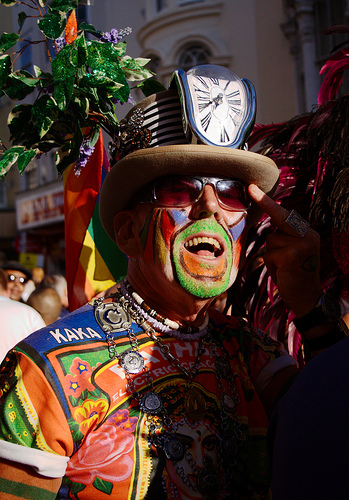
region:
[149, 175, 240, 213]
A man wearing sunglasses.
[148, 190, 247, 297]
The man face is painted.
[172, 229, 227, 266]
The man mouth is open.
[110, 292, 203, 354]
Beaded necklace around the man neck.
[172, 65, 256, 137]
A clock on the man head.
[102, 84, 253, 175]
The man is wearing a hat.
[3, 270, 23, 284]
The man is wearing glasses.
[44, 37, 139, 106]
Leaves on top of the hat.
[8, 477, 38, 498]
A green line on the man arm.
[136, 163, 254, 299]
Paint on a man's face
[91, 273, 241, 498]
Four necklaces on a man's neck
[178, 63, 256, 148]
Blue framed white analog clock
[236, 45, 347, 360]
Dark pink feather headdress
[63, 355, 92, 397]
Two peach flowers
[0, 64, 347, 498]
Man wearing colorful clothing and a hat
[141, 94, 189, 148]
Black and white stripes around a hat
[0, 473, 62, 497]
Green painted stripe on an arm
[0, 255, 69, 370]
Crowd of people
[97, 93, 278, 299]
man wearing a top hat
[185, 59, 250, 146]
clock face on a top hat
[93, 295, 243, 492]
man wearing a silver medallion necklace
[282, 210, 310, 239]
man wearing a silver ring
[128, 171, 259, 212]
man wearing sunglasses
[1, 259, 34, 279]
man wearing a black hat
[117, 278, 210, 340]
man wearing a puka shell necklace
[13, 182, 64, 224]
red and white sign above a store entrance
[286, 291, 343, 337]
man wearing a watch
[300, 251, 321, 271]
man with an eyeball drawn on his hand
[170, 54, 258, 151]
A melted blue clock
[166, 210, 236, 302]
A bright green beard and mustache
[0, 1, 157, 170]
An artificial tree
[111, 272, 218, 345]
A white beaded necklace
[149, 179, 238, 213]
A pair of sunglasses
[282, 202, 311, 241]
A silver ring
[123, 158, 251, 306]
A man's face with colorful paint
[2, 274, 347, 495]
A brightly colored shirt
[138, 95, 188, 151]
White and black stripes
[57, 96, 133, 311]
A large rainbow flag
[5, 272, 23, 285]
black glasses worn by the person in the crowd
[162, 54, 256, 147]
clock on man's head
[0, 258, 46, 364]
man wearing a white tee shirt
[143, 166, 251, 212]
sunglasses worn by man in the front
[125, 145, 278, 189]
brown rim of man's hat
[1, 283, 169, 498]
multi-colored shirt man is wearing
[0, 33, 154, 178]
green plant hanging above the man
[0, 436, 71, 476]
white strip on sleeve of the shirt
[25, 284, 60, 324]
balled head of a man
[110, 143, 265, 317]
man with paint on face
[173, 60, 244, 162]
man wearing hat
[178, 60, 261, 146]
black and white clock face on hat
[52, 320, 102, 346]
white letters on shirt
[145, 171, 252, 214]
glasses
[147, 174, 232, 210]
brown glasses worn by man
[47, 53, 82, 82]
green leaves in hat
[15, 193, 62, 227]
red and white colored sign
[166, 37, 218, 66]
window in tan tower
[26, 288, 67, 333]
A person is standing up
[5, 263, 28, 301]
A person is standing up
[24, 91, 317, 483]
A person is standing up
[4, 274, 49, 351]
A person is standing up